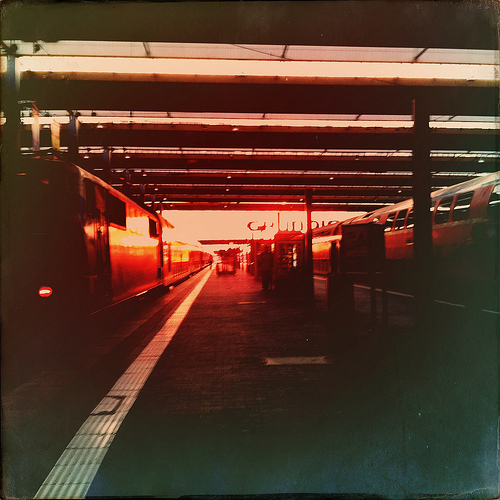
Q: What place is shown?
A: It is a station.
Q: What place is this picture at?
A: It is at the station.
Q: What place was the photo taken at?
A: It was taken at the station.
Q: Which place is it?
A: It is a station.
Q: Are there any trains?
A: Yes, there is a train.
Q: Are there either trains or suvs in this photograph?
A: Yes, there is a train.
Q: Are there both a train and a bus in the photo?
A: No, there is a train but no buses.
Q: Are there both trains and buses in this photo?
A: No, there is a train but no buses.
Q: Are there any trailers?
A: No, there are no trailers.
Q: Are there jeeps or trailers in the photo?
A: No, there are no trailers or jeeps.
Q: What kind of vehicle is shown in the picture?
A: The vehicle is a train.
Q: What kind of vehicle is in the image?
A: The vehicle is a train.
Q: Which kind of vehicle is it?
A: The vehicle is a train.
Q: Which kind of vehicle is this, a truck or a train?
A: This is a train.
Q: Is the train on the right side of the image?
A: Yes, the train is on the right of the image.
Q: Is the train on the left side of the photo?
A: No, the train is on the right of the image.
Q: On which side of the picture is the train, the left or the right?
A: The train is on the right of the image.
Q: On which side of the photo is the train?
A: The train is on the right of the image.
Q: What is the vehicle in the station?
A: The vehicle is a train.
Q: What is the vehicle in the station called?
A: The vehicle is a train.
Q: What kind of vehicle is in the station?
A: The vehicle is a train.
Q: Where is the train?
A: The train is in the station.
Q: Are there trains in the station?
A: Yes, there is a train in the station.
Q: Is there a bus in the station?
A: No, there is a train in the station.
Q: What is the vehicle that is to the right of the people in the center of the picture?
A: The vehicle is a train.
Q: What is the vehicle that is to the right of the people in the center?
A: The vehicle is a train.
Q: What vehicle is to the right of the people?
A: The vehicle is a train.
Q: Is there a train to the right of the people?
A: Yes, there is a train to the right of the people.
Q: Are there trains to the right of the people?
A: Yes, there is a train to the right of the people.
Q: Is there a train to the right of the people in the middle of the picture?
A: Yes, there is a train to the right of the people.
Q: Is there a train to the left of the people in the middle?
A: No, the train is to the right of the people.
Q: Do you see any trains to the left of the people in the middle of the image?
A: No, the train is to the right of the people.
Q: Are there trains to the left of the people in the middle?
A: No, the train is to the right of the people.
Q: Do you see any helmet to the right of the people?
A: No, there is a train to the right of the people.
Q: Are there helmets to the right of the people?
A: No, there is a train to the right of the people.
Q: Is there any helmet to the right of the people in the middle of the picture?
A: No, there is a train to the right of the people.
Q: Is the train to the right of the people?
A: Yes, the train is to the right of the people.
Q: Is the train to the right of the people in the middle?
A: Yes, the train is to the right of the people.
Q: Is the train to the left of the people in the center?
A: No, the train is to the right of the people.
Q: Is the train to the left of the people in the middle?
A: No, the train is to the right of the people.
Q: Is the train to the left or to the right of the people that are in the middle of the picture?
A: The train is to the right of the people.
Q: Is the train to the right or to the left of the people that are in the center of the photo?
A: The train is to the right of the people.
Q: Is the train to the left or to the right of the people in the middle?
A: The train is to the right of the people.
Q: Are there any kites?
A: No, there are no kites.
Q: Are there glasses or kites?
A: No, there are no kites or glasses.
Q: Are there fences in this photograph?
A: No, there are no fences.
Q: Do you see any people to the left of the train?
A: Yes, there are people to the left of the train.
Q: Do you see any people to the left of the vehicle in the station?
A: Yes, there are people to the left of the train.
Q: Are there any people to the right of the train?
A: No, the people are to the left of the train.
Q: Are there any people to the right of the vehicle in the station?
A: No, the people are to the left of the train.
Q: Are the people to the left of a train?
A: Yes, the people are to the left of a train.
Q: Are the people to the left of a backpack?
A: No, the people are to the left of a train.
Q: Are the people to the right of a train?
A: No, the people are to the left of a train.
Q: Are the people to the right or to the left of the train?
A: The people are to the left of the train.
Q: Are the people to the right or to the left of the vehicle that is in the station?
A: The people are to the left of the train.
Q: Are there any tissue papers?
A: No, there are no tissue papers.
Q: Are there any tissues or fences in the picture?
A: No, there are no tissues or fences.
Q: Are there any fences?
A: No, there are no fences.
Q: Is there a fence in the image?
A: No, there are no fences.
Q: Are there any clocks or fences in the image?
A: No, there are no fences or clocks.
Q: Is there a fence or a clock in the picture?
A: No, there are no fences or clocks.